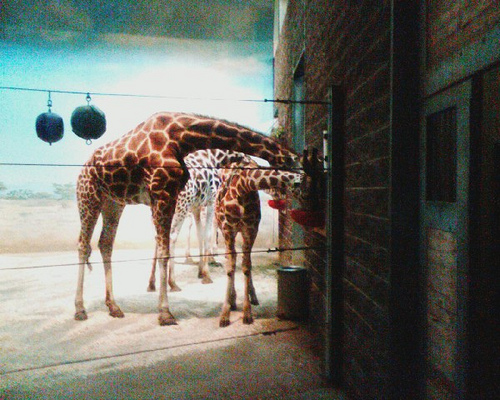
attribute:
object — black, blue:
[69, 102, 106, 140]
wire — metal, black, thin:
[0, 87, 335, 107]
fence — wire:
[0, 88, 338, 385]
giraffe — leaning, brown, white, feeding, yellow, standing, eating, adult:
[74, 108, 320, 331]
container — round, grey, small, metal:
[276, 264, 311, 322]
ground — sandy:
[6, 251, 328, 399]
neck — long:
[173, 113, 304, 179]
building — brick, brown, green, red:
[272, 37, 499, 399]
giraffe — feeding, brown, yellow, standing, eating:
[212, 148, 320, 313]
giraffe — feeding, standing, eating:
[157, 145, 227, 270]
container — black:
[36, 112, 64, 143]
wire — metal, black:
[0, 154, 338, 180]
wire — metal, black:
[1, 244, 330, 274]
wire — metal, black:
[2, 319, 325, 378]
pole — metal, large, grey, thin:
[325, 85, 348, 382]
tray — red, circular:
[291, 207, 329, 228]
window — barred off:
[422, 108, 459, 204]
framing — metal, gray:
[417, 77, 471, 236]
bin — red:
[268, 194, 288, 214]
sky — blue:
[1, 0, 282, 201]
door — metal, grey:
[283, 61, 308, 299]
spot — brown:
[147, 151, 166, 171]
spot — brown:
[227, 205, 243, 218]